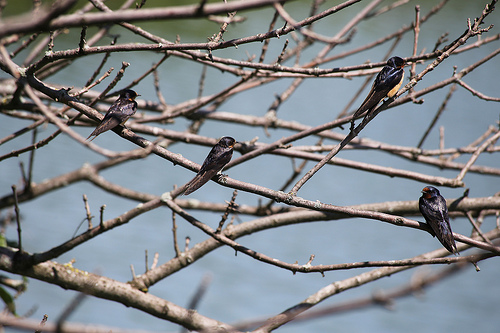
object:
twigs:
[75, 192, 110, 233]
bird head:
[418, 180, 443, 197]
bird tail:
[183, 166, 220, 198]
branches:
[169, 20, 498, 69]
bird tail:
[81, 108, 132, 140]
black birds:
[87, 88, 462, 253]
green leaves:
[0, 158, 45, 330]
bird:
[347, 49, 420, 126]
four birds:
[85, 54, 462, 254]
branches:
[1, 1, 496, 329]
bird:
[417, 184, 456, 251]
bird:
[185, 136, 238, 193]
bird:
[352, 57, 404, 123]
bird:
[90, 89, 142, 147]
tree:
[0, 3, 499, 330]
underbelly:
[389, 70, 404, 98]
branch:
[161, 192, 407, 265]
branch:
[213, 36, 498, 75]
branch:
[41, 3, 368, 69]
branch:
[7, 210, 358, 327]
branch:
[3, 0, 291, 40]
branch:
[6, 94, 461, 189]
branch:
[260, 223, 499, 333]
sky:
[1, 3, 499, 332]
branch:
[31, 63, 498, 256]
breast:
[388, 75, 402, 96]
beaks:
[424, 187, 430, 197]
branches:
[210, 198, 377, 243]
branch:
[284, 110, 354, 144]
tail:
[354, 97, 377, 119]